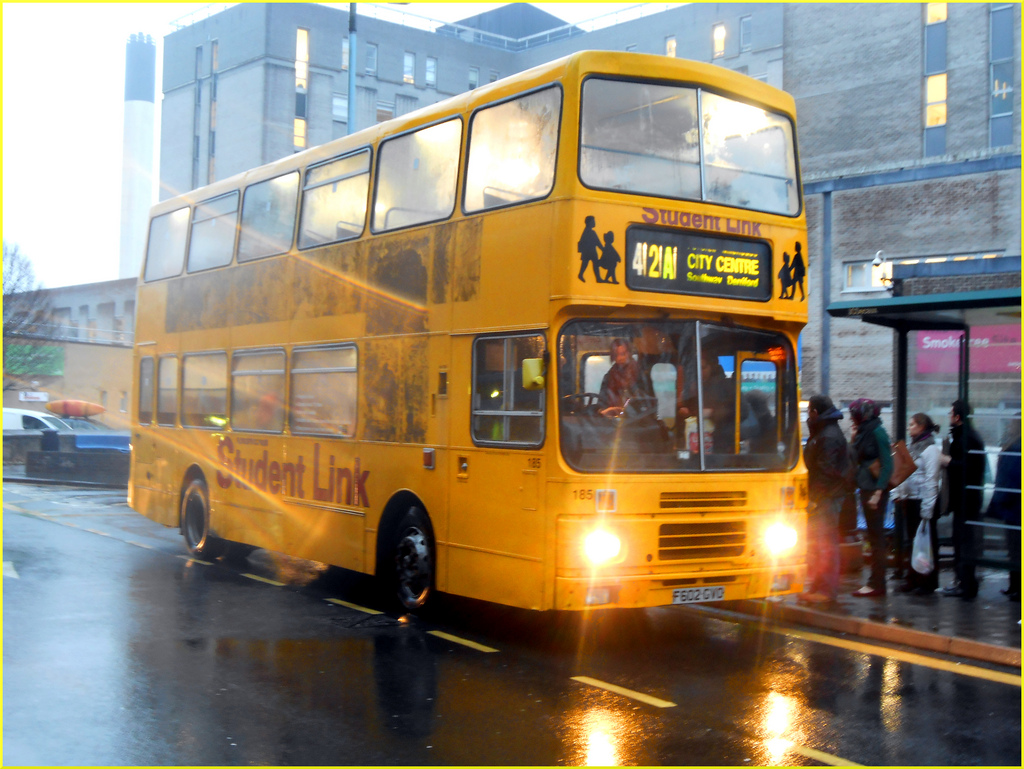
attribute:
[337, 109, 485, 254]
window — glass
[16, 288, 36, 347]
leaves — green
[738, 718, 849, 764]
line — small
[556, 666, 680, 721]
line — yellow, small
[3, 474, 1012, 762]
road — yellow, small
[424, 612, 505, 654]
line — small, yellow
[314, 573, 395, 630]
line — yellow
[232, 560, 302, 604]
line — small, yellow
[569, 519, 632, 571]
right light — white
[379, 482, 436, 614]
wheel — black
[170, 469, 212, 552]
wheel — black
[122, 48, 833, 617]
bus — yellow, double-decker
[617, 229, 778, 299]
lcd — yellow